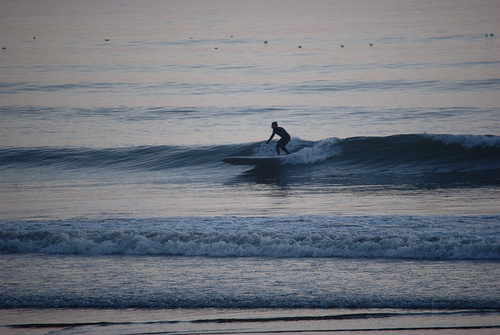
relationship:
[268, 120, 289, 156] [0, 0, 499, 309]
person on water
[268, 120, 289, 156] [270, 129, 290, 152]
person in wetsuit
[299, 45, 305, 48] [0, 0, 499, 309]
object floating on water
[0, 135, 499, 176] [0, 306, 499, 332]
wave rolling on shore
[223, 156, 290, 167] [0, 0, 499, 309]
surfboard on water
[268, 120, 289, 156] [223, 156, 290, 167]
person on surfboard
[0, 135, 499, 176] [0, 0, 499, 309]
wave on water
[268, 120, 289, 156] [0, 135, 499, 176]
person riding wave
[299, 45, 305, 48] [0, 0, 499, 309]
object in water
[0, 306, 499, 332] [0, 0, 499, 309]
shore next to water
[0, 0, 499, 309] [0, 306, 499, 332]
water coming to shore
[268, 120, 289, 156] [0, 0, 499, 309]
person in water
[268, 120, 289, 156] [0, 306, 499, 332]
person near shore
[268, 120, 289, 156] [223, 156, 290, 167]
person standing ont surfboard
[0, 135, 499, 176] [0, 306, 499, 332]
wave washing on shore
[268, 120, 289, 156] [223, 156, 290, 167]
person standing on surfboard